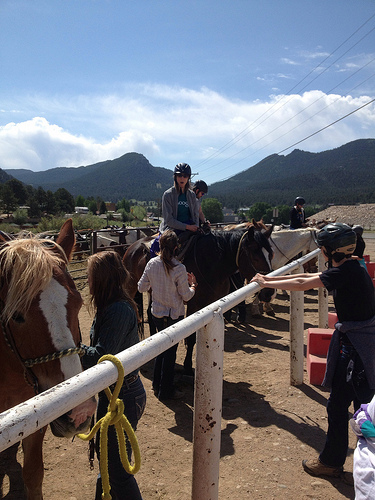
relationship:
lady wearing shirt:
[135, 227, 198, 399] [137, 256, 194, 318]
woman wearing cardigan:
[159, 163, 206, 232] [162, 178, 202, 232]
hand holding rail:
[252, 274, 275, 287] [211, 281, 257, 325]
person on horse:
[161, 161, 202, 248] [1, 216, 98, 496]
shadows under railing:
[165, 371, 333, 463] [114, 261, 319, 456]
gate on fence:
[69, 229, 92, 278] [89, 227, 162, 259]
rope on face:
[22, 345, 87, 371] [1, 218, 97, 437]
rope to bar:
[78, 352, 141, 497] [0, 247, 322, 452]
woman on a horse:
[164, 156, 206, 225] [202, 228, 281, 283]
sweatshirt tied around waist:
[317, 312, 374, 391] [331, 316, 374, 343]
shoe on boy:
[301, 457, 344, 478] [251, 220, 374, 477]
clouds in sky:
[0, 78, 375, 185] [1, 0, 373, 183]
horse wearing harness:
[117, 217, 275, 372] [221, 220, 246, 269]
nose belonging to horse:
[262, 283, 279, 296] [117, 217, 275, 372]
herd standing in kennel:
[29, 222, 157, 260] [2, 220, 162, 279]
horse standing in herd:
[87, 227, 146, 244] [29, 222, 157, 260]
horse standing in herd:
[86, 233, 121, 254] [29, 222, 157, 260]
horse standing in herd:
[42, 232, 90, 257] [29, 222, 157, 260]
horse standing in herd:
[139, 224, 155, 233] [29, 222, 157, 260]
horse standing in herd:
[75, 227, 95, 235] [29, 222, 157, 260]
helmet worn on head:
[313, 222, 357, 257] [318, 231, 356, 263]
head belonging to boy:
[318, 231, 356, 263] [249, 220, 360, 477]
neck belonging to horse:
[268, 226, 318, 258] [251, 224, 322, 316]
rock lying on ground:
[273, 456, 280, 462] [1, 204, 363, 497]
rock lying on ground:
[240, 419, 248, 425] [1, 204, 363, 497]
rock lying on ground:
[242, 434, 252, 438] [1, 204, 363, 497]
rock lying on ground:
[281, 456, 287, 462] [1, 204, 363, 497]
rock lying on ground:
[225, 454, 231, 459] [1, 204, 363, 497]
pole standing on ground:
[198, 324, 226, 498] [28, 251, 373, 497]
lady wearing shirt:
[135, 227, 198, 399] [135, 252, 194, 320]